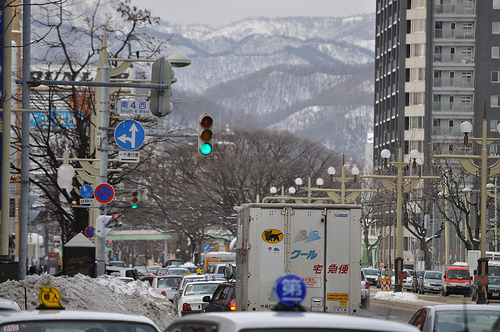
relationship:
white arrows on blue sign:
[113, 119, 145, 151] [108, 112, 149, 156]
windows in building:
[426, 8, 468, 123] [372, 0, 498, 289]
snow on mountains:
[116, 12, 361, 72] [21, 0, 377, 171]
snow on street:
[2, 270, 179, 321] [358, 284, 489, 329]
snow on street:
[373, 286, 418, 303] [358, 284, 489, 329]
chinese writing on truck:
[288, 245, 317, 259] [231, 201, 366, 308]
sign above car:
[32, 278, 67, 308] [7, 308, 149, 328]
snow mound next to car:
[3, 272, 172, 324] [169, 280, 240, 315]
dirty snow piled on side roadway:
[24, 281, 200, 311] [379, 258, 445, 325]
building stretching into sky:
[372, 0, 498, 289] [25, 1, 373, 26]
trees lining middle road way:
[111, 103, 313, 268] [7, 264, 491, 328]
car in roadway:
[407, 303, 497, 330] [364, 283, 500, 316]